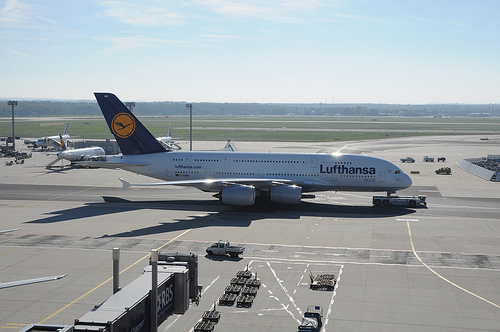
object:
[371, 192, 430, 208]
vehicle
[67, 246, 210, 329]
boarding walkway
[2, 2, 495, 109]
sky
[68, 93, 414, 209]
airplane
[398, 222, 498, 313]
line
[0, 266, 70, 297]
wing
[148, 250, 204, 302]
ramp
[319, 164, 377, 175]
name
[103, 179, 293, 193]
wing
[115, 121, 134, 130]
bird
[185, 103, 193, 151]
light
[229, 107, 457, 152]
runway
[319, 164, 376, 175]
logo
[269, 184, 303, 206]
turbines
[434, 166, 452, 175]
cars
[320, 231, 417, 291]
ground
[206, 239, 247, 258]
truck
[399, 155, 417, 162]
vehicles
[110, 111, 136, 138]
circle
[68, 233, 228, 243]
lines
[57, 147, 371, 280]
runway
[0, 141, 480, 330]
tarmac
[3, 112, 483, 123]
runway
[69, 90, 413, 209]
plane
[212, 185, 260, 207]
engine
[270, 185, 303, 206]
engine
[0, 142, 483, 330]
airway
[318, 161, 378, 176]
word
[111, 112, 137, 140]
logo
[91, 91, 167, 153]
tail